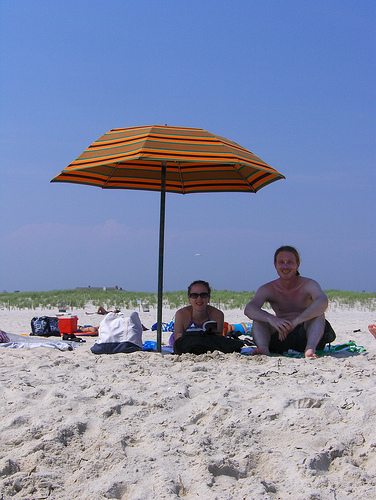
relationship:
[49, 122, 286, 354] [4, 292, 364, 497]
umbrella on beach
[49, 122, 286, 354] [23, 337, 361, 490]
umbrella in sand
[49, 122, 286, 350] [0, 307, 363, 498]
umbrella in sand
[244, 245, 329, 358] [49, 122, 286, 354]
man sitting under umbrella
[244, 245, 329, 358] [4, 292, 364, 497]
man sitting on beach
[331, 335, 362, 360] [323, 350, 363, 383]
green towel on sand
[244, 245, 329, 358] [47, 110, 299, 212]
man under umbrella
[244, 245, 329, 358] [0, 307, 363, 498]
man sitting in sand